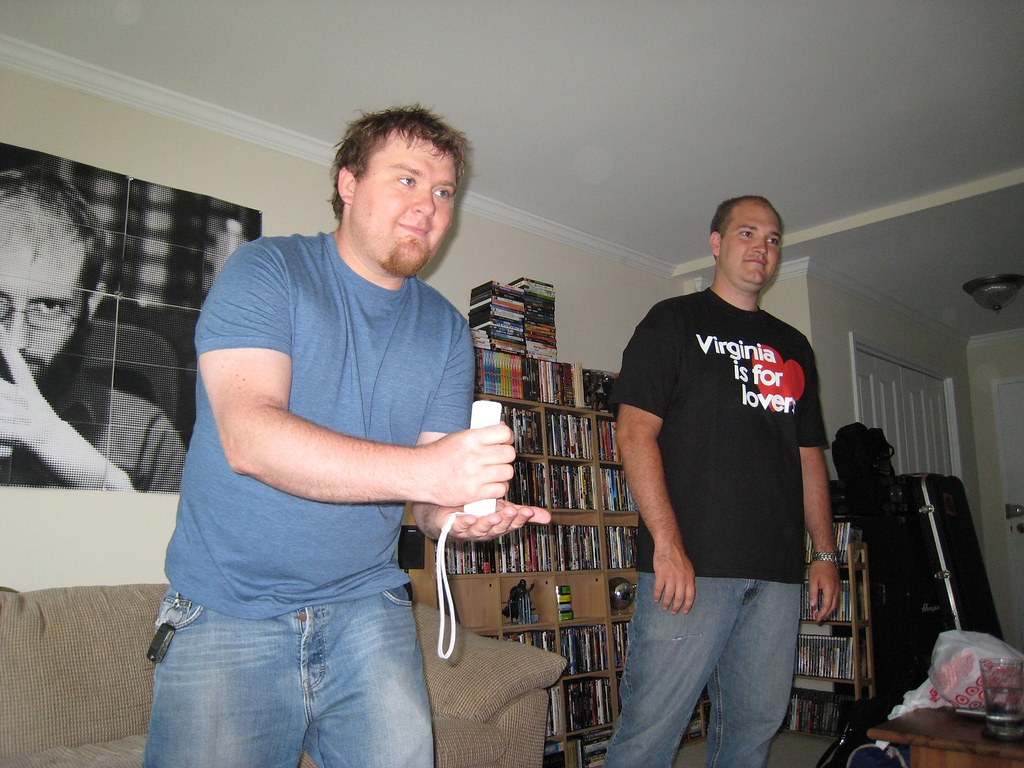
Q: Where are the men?
A: Living room.